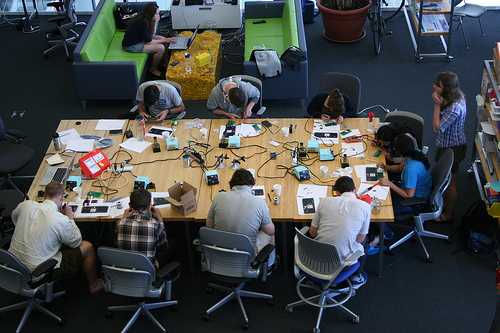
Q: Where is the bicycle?
A: By the flower pot.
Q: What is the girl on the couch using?
A: A laptop.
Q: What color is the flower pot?
A: Brown.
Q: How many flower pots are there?
A: One.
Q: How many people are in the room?
A: Eleven.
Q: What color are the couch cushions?
A: Green.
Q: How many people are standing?
A: One.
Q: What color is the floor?
A: Blue.